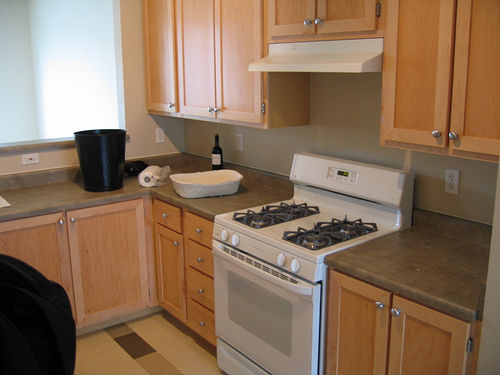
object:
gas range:
[210, 154, 414, 375]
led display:
[336, 171, 350, 177]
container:
[169, 169, 245, 199]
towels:
[138, 164, 170, 188]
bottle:
[211, 133, 223, 173]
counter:
[0, 176, 154, 332]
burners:
[277, 215, 377, 251]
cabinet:
[151, 197, 188, 325]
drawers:
[182, 207, 215, 248]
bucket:
[73, 127, 128, 192]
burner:
[230, 198, 320, 230]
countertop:
[10, 179, 95, 218]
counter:
[150, 171, 285, 346]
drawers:
[182, 234, 213, 279]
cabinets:
[140, 0, 270, 126]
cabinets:
[378, 0, 500, 154]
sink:
[0, 194, 12, 210]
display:
[326, 166, 360, 186]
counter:
[325, 228, 486, 375]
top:
[409, 233, 464, 282]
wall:
[315, 81, 370, 147]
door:
[216, 282, 320, 340]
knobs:
[286, 258, 300, 273]